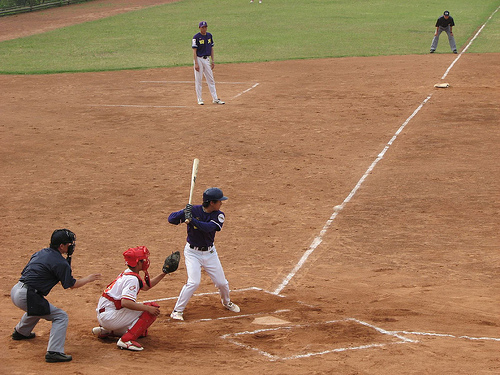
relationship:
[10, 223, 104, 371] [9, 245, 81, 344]
catcher in uniform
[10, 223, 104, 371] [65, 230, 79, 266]
catcher in mask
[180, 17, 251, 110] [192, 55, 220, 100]
man wearing pants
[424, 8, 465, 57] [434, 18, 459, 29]
umpire wearing shirt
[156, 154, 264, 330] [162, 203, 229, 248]
batter in blue uniform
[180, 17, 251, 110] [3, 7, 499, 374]
man on field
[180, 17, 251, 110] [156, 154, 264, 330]
man near batter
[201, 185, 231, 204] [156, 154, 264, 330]
helmet on batter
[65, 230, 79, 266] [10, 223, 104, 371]
mask on catcher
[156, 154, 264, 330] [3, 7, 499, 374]
batter on field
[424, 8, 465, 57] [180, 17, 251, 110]
umpire near man